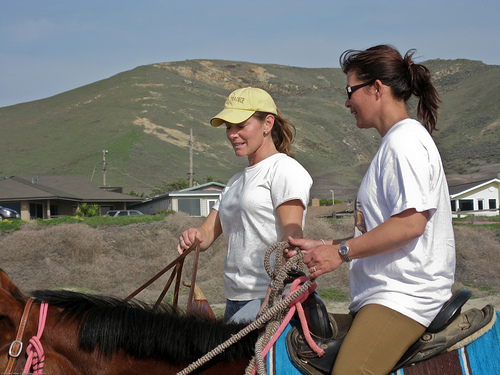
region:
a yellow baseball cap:
[207, 84, 282, 129]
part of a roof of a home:
[443, 179, 482, 196]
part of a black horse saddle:
[289, 282, 471, 369]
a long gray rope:
[167, 255, 315, 372]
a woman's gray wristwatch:
[337, 235, 358, 264]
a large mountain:
[1, 57, 496, 185]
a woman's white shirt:
[212, 153, 314, 303]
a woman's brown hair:
[332, 43, 445, 133]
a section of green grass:
[27, 210, 166, 227]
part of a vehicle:
[103, 201, 141, 218]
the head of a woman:
[217, 83, 304, 157]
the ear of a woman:
[249, 106, 284, 148]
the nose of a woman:
[220, 125, 250, 151]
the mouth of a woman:
[220, 138, 260, 163]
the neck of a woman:
[228, 130, 303, 190]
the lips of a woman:
[226, 139, 251, 154]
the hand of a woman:
[168, 203, 223, 268]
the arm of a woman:
[288, 195, 442, 300]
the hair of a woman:
[328, 36, 453, 147]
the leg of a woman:
[324, 255, 454, 366]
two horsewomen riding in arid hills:
[0, 42, 497, 372]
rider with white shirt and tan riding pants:
[0, 42, 497, 373]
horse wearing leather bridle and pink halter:
[2, 274, 497, 374]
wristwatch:
[338, 243, 349, 260]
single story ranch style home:
[1, 178, 150, 220]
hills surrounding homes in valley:
[0, 57, 498, 202]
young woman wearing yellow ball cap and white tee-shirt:
[176, 86, 313, 317]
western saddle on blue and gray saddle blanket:
[265, 248, 498, 373]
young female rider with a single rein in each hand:
[5, 44, 499, 372]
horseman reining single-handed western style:
[2, 87, 313, 321]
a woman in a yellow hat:
[173, 85, 313, 321]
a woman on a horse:
[286, 42, 455, 369]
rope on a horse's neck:
[19, 300, 49, 373]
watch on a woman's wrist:
[338, 238, 352, 263]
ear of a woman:
[263, 111, 273, 133]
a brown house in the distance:
[1, 173, 143, 217]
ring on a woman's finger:
[310, 263, 319, 271]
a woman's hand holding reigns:
[128, 228, 203, 307]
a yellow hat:
[208, 85, 282, 123]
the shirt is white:
[348, 116, 459, 324]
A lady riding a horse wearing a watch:
[285, 40, 460, 372]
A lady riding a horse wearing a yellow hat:
[177, 80, 314, 327]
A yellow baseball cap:
[209, 83, 280, 125]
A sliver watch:
[335, 237, 350, 264]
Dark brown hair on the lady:
[336, 42, 449, 134]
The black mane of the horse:
[29, 287, 264, 369]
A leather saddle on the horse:
[275, 286, 496, 373]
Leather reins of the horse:
[118, 236, 209, 312]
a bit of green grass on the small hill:
[5, 213, 176, 227]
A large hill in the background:
[3, 56, 497, 201]